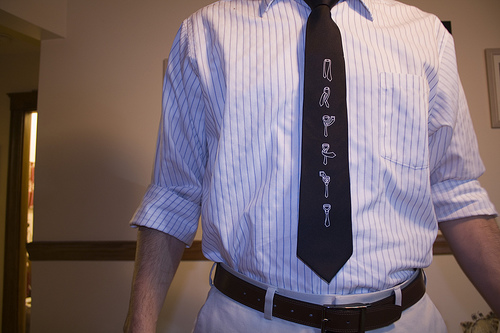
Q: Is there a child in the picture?
A: No, there are no children.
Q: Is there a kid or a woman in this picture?
A: No, there are no children or women.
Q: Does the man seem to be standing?
A: Yes, the man is standing.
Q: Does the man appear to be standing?
A: Yes, the man is standing.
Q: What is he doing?
A: The man is standing.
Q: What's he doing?
A: The man is standing.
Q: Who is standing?
A: The man is standing.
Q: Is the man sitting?
A: No, the man is standing.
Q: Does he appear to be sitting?
A: No, the man is standing.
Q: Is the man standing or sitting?
A: The man is standing.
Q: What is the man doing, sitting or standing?
A: The man is standing.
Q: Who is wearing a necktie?
A: The man is wearing a necktie.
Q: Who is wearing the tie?
A: The man is wearing a necktie.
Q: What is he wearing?
A: The man is wearing a necktie.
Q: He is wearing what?
A: The man is wearing a necktie.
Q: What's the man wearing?
A: The man is wearing a necktie.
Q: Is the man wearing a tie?
A: Yes, the man is wearing a tie.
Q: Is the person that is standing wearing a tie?
A: Yes, the man is wearing a tie.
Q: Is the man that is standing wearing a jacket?
A: No, the man is wearing a tie.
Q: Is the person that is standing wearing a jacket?
A: No, the man is wearing a tie.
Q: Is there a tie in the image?
A: Yes, there is a tie.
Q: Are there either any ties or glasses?
A: Yes, there is a tie.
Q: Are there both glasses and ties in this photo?
A: No, there is a tie but no glasses.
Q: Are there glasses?
A: No, there are no glasses.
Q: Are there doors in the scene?
A: Yes, there is a door.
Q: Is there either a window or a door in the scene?
A: Yes, there is a door.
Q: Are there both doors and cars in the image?
A: No, there is a door but no cars.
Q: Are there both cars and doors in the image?
A: No, there is a door but no cars.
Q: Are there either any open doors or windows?
A: Yes, there is an open door.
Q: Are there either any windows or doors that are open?
A: Yes, the door is open.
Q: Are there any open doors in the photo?
A: Yes, there is an open door.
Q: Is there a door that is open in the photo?
A: Yes, there is an open door.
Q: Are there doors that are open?
A: Yes, there is a door that is open.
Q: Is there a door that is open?
A: Yes, there is a door that is open.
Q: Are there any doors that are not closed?
A: Yes, there is a open door.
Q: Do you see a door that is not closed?
A: Yes, there is a open door.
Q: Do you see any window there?
A: No, there are no windows.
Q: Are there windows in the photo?
A: No, there are no windows.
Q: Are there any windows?
A: No, there are no windows.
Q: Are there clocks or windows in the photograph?
A: No, there are no windows or clocks.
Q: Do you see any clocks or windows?
A: No, there are no windows or clocks.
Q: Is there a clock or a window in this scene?
A: No, there are no windows or clocks.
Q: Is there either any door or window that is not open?
A: No, there is a door but it is open.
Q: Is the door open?
A: Yes, the door is open.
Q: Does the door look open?
A: Yes, the door is open.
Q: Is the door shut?
A: No, the door is open.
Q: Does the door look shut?
A: No, the door is open.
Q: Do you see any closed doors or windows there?
A: No, there is a door but it is open.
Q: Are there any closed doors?
A: No, there is a door but it is open.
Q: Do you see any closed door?
A: No, there is a door but it is open.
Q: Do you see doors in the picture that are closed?
A: No, there is a door but it is open.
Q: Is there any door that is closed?
A: No, there is a door but it is open.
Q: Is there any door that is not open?
A: No, there is a door but it is open.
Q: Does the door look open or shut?
A: The door is open.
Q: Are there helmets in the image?
A: No, there are no helmets.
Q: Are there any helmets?
A: No, there are no helmets.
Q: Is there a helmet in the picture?
A: No, there are no helmets.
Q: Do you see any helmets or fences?
A: No, there are no helmets or fences.